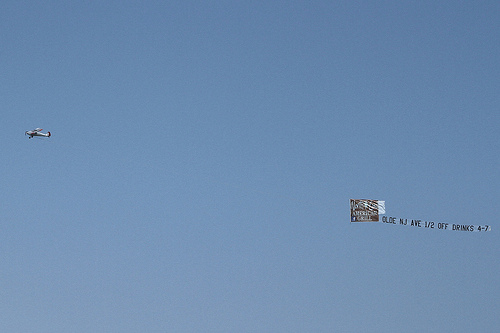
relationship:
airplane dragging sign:
[25, 127, 51, 139] [341, 194, 495, 237]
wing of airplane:
[35, 128, 48, 138] [25, 127, 51, 139]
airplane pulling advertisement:
[26, 124, 49, 140] [350, 198, 491, 233]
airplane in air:
[25, 127, 51, 139] [215, 88, 218, 91]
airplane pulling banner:
[25, 127, 51, 139] [350, 200, 491, 234]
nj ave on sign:
[398, 216, 424, 226] [348, 197, 495, 234]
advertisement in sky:
[350, 198, 491, 233] [2, 2, 499, 332]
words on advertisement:
[379, 216, 490, 232] [350, 198, 491, 233]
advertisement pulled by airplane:
[350, 198, 491, 233] [24, 119, 57, 158]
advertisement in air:
[350, 157, 491, 269] [245, 230, 364, 311]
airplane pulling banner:
[25, 127, 51, 139] [344, 198, 478, 272]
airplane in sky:
[25, 127, 51, 139] [193, 153, 291, 236]